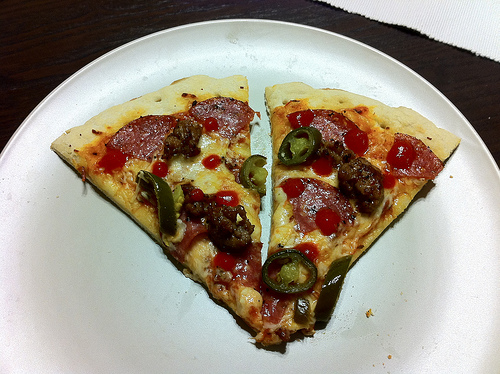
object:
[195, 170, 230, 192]
cheese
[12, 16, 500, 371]
plate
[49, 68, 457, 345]
pizza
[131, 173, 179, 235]
jalapeno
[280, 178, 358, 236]
pepperoni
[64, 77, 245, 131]
crust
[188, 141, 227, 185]
cheese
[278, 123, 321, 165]
pepper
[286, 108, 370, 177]
tomato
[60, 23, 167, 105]
mat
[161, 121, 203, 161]
meat